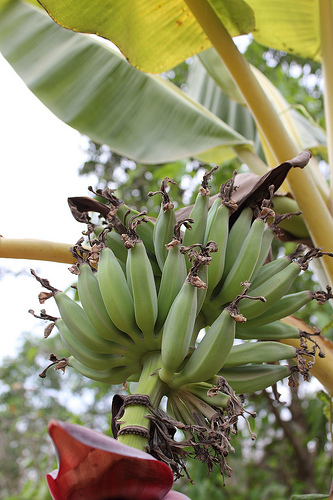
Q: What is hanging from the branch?
A: Fruit.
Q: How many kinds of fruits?
A: One.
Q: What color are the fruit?
A: Green.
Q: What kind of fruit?
A: Banana.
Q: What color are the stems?
A: Yellow.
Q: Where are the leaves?
A: Above the fruit.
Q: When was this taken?
A: During the day.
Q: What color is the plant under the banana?
A: Red.